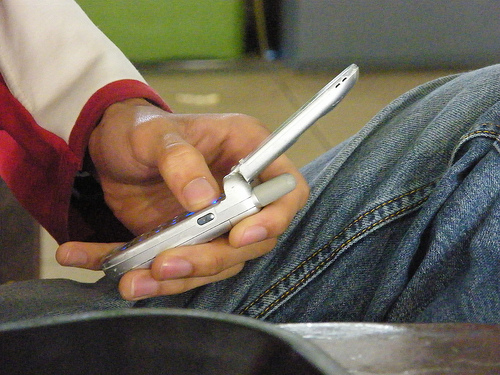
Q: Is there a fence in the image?
A: No, there are no fences.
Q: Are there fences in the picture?
A: No, there are no fences.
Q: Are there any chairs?
A: No, there are no chairs.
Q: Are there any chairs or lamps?
A: No, there are no chairs or lamps.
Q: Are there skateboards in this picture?
A: No, there are no skateboards.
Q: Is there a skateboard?
A: No, there are no skateboards.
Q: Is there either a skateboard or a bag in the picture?
A: No, there are no skateboards or bags.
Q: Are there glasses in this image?
A: No, there are no glasses.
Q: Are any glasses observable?
A: No, there are no glasses.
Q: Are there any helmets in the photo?
A: No, there are no helmets.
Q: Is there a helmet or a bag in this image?
A: No, there are no helmets or bags.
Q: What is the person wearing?
A: The person is wearing jeans.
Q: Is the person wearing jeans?
A: Yes, the person is wearing jeans.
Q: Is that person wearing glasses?
A: No, the person is wearing jeans.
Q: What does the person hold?
A: The person holds the cell phone.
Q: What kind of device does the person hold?
A: The person holds the cellphone.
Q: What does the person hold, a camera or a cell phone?
A: The person holds a cell phone.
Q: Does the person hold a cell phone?
A: Yes, the person holds a cell phone.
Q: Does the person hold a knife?
A: No, the person holds a cell phone.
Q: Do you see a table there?
A: Yes, there is a table.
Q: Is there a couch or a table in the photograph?
A: Yes, there is a table.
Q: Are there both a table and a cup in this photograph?
A: No, there is a table but no cups.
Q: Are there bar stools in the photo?
A: No, there are no bar stools.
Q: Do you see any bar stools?
A: No, there are no bar stools.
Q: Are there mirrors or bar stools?
A: No, there are no bar stools or mirrors.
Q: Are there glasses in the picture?
A: No, there are no glasses.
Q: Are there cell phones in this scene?
A: Yes, there is a cell phone.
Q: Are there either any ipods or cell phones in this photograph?
A: Yes, there is a cell phone.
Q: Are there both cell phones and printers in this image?
A: No, there is a cell phone but no printers.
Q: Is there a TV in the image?
A: No, there are no televisions.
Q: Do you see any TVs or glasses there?
A: No, there are no TVs or glasses.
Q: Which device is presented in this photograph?
A: The device is a cell phone.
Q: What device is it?
A: The device is a cell phone.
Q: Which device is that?
A: This is a cell phone.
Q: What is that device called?
A: This is a cell phone.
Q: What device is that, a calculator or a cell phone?
A: This is a cell phone.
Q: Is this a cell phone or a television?
A: This is a cell phone.